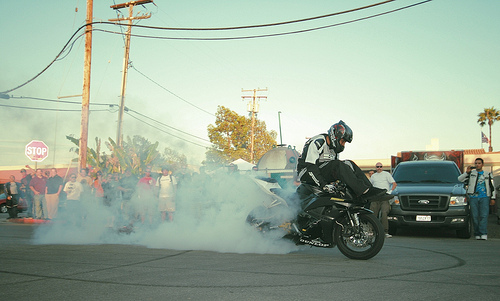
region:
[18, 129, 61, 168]
a red stop sign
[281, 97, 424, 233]
a man wearing a helmet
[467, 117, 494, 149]
the american flag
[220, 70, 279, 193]
a wooden telephone post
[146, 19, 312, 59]
some black electrical wires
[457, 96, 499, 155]
a tall, single palm tree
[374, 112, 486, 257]
a dark ford truck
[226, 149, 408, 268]
a black suzuki motorcycle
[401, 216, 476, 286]
skid marks on pavement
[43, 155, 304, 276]
a cloud of smoke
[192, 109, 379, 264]
man doing motorcycle trick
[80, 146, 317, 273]
smoke streaming from motorcycle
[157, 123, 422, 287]
man on black motorcycle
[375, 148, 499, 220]
two men next to pickup truck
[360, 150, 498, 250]
men leaning on Ford truck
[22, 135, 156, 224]
people gathered around stop sign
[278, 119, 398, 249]
man with legs over handlebars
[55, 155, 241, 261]
people obscured by smoke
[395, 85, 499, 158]
palm tree and American flag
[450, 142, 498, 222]
man recording motorcycle trick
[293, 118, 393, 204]
person riding the motorcycle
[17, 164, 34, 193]
man near stop sign with fist in the air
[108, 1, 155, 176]
closest power pole with cross bars on top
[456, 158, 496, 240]
man taking picture on the right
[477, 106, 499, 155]
palm tree on the right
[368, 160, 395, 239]
bald man in white shirt and sunglasses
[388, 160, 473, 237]
dark gray or black Ford pickup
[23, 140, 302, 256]
smoke coming from motorcycle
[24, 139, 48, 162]
stop sign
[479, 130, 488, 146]
flag near palm tree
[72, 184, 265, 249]
Smoke coming from motorcycle tires.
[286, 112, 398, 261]
Man performing motorcycle tricks.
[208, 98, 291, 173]
Green trees in background.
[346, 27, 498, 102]
Clear blue sky.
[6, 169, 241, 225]
Crowd of people watching the motorcyclist.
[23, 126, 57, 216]
Red and white stop sign.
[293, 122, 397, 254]
Man wearing black helmet.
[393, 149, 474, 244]
Black ford pickup truck.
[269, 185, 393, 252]
Black and white motorcycle.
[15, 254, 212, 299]
Skid marks on asphalt from motorcycle.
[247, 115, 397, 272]
man riding a motorcycle backwards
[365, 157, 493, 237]
men leaning on a truck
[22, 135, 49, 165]
a red stop sign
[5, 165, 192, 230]
a crowd of people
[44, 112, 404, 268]
motorcycle giving off a lot of smoke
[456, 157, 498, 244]
man taking a photograph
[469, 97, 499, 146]
a palm tree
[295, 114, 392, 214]
man in a motorcycle helmet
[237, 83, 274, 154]
a telephone pole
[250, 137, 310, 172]
a building with a dome roof